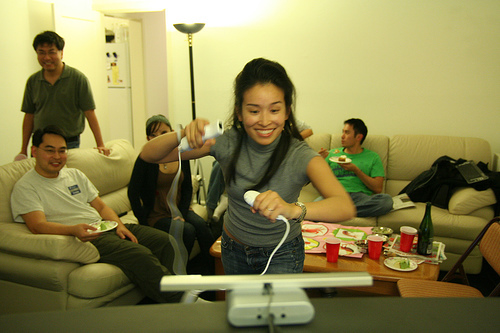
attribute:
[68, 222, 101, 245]
hand — plate 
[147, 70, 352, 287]
lady — holding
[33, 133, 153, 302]
man — holding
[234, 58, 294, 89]
hair — dark , long 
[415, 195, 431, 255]
bottle — Green  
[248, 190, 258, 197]
nunchuck — white 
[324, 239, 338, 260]
cup — red  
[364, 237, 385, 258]
cup — red  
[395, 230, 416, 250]
cup — red  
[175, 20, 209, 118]
lamp — tall , black 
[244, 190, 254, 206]
controller — white 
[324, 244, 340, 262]
cup — red 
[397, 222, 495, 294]
chair — brown 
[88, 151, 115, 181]
couch — cream , colored 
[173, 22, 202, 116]
light — tall 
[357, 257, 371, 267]
coffee table — wooden 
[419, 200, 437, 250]
bottle — green 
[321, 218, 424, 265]
cups on the table — red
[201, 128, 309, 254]
lady in grey shirt — wearing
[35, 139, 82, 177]
smiling man — wearing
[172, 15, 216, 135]
gold stand lamp — Black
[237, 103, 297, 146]
big smile — Woman, face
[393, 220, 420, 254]
red plastic cup — plastic 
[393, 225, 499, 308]
foldable chair — foldable 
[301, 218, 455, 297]
wooden coffee table — brown, light 